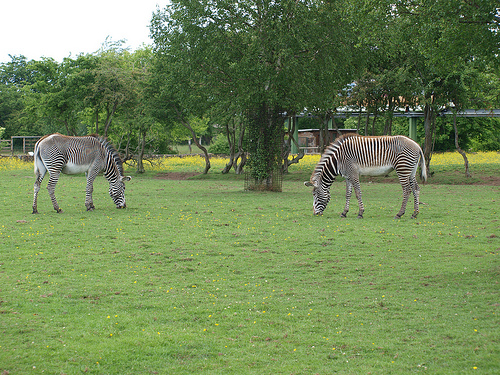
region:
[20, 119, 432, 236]
two zebras standing in field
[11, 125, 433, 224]
two zebras grazing in grass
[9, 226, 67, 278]
section of yellow flowers in green grass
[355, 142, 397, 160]
black and white striped pattern on zebra fur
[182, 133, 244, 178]
brown tree branches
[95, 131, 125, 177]
black and white zebra mane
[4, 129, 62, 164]
wooden fence on edge of green field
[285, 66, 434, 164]
house behind trees and foliage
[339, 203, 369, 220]
two zebra hooves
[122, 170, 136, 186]
one zebra ear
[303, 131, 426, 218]
black and white grazing zebra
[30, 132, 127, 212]
black and white zebra grazing on grass in field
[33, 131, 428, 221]
pair of grazing black and white zebras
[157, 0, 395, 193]
large tree in zebra compound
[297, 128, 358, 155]
building in wild animal park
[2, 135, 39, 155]
wooden fence in wild animal park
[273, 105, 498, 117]
shade shelter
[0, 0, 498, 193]
trees in animal compound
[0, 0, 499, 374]
two black and white zebras in wild animal compound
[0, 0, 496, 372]
wild animal park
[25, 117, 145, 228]
White and black zebra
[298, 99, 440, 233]
White and black zebra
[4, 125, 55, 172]
Small brown wooden fence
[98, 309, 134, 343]
Yellow flowers in field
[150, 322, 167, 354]
Yellow flowers in field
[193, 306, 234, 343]
Yellow flowers in field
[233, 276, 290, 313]
Yellow flowers in field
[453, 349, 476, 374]
Yellow flowers in field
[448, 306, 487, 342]
Yellow flowers in field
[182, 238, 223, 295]
Yellow flowers in field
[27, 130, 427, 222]
two zebras grazing in a field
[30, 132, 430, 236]
two zebras eating green grass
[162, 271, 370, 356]
small yellow wildflowers on the ground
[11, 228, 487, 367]
green grass and small yellow wildflowers on the ground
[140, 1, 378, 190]
a green leaf tree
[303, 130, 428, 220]
a zebra standing near another zebra eating grass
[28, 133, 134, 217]
a zebra grazing in a field with another zebra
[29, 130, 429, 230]
two black and white zebras eating green grass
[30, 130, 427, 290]
two zebras eating grass in an open field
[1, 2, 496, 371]
zebras in a wildlife park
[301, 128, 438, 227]
black and white zebra grazing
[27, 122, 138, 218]
black and white zebra grazing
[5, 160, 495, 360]
green enclosed field for zebras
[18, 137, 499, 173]
yellow dandelions throughout field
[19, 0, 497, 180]
green trees bordering field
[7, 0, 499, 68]
sunny and white clear sky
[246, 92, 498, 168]
metal fence in background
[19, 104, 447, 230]
two zebras face each other with face in ground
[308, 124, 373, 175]
black and white striped mane of zebra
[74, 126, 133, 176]
black and white striped mane of zebra